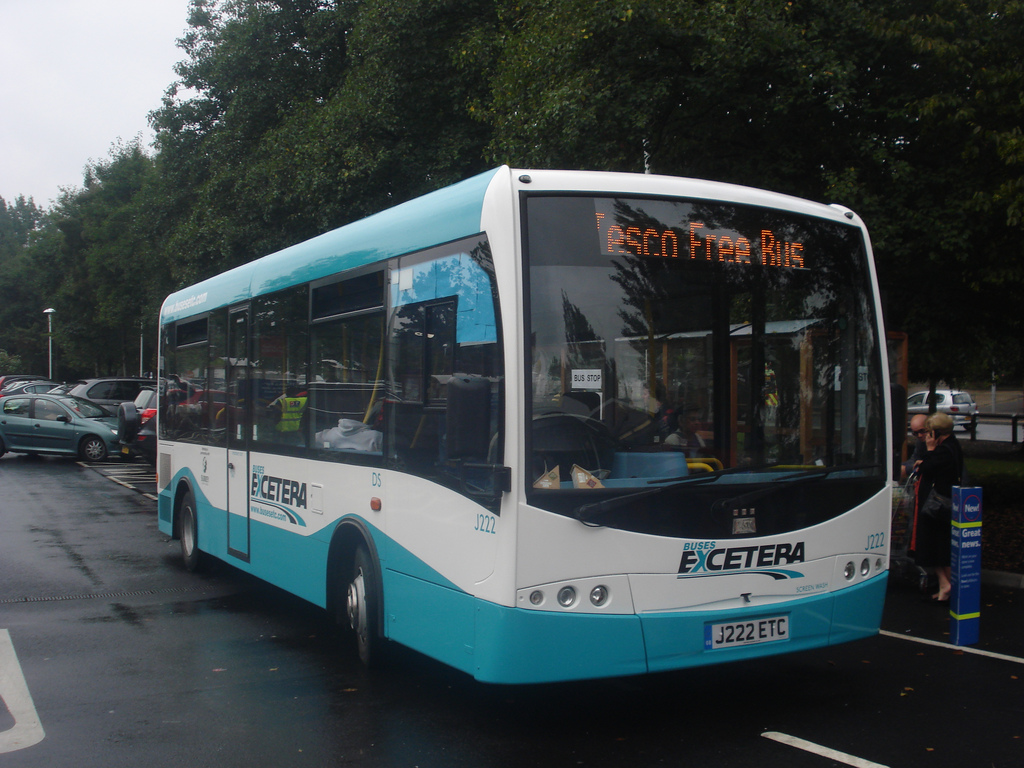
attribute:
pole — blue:
[952, 484, 985, 653]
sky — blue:
[15, 1, 196, 145]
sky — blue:
[7, 9, 224, 234]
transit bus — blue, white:
[106, 149, 910, 720]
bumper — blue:
[465, 559, 950, 673]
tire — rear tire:
[171, 487, 197, 573]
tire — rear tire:
[330, 531, 381, 677]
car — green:
[2, 392, 124, 463]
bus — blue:
[102, 142, 925, 703]